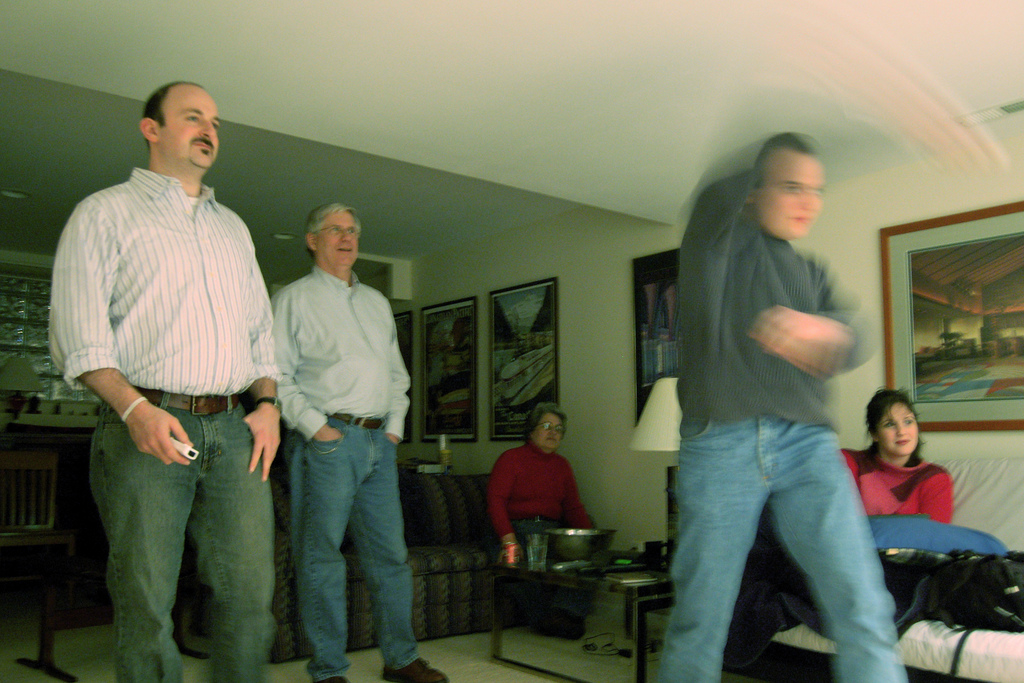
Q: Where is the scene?
A: In a living room.